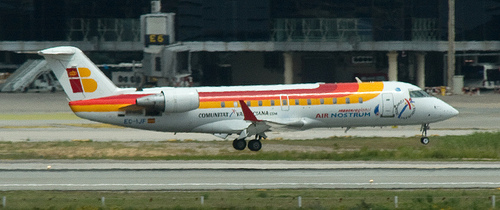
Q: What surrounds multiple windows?
A: Stripe of yellow orange paint.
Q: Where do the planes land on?
A: Airport runway.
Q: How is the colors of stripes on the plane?
A: Red, orange and yellow.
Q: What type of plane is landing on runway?
A: Small airplane.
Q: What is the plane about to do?
A: To land on the runway.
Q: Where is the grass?
A: Between the runway on each side.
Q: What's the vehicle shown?
A: Airplane.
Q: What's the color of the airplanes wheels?
A: Black.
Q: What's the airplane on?
A: Runway.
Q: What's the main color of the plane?
A: White.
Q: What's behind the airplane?
A: Airport.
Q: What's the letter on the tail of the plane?
A: B.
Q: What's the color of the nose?
A: White.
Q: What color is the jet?
A: Orange, red and white.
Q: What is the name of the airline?
A: Air Nostrum.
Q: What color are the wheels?
A: Black and white.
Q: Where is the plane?
A: At the airport.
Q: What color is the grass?
A: Green.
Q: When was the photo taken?
A: In daytime.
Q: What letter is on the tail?
A: B.